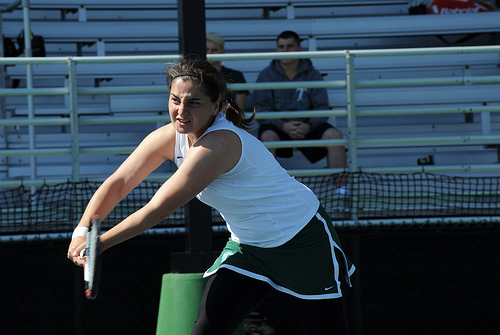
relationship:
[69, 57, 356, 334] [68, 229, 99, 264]
tennis player has hands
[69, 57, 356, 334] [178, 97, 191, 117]
tennis player has nose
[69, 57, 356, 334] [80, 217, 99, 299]
tennis player holds racket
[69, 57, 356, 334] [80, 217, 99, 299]
tennis player holding racket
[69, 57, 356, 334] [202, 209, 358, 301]
tennis player wearing skirt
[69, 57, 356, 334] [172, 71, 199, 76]
tennis player wears headband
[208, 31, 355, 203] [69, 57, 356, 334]
men are behind tennis player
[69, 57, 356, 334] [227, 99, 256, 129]
tennis player has ponytail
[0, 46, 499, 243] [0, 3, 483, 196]
fence on bleachers